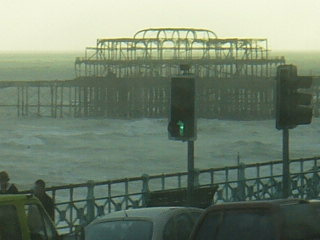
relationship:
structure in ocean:
[67, 32, 285, 94] [18, 112, 226, 173]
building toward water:
[79, 33, 283, 118] [11, 112, 132, 165]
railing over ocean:
[0, 153, 318, 239] [30, 133, 206, 173]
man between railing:
[25, 177, 55, 230] [72, 160, 310, 216]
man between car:
[25, 177, 55, 230] [2, 194, 52, 238]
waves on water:
[15, 125, 123, 146] [7, 116, 167, 160]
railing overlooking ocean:
[0, 153, 318, 239] [2, 49, 317, 235]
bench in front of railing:
[142, 182, 218, 205] [0, 153, 318, 239]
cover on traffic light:
[295, 74, 312, 88] [273, 61, 314, 129]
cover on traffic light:
[293, 91, 312, 107] [273, 61, 314, 129]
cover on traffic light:
[295, 106, 311, 129] [273, 61, 314, 129]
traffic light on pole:
[273, 61, 314, 129] [281, 127, 292, 199]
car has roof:
[66, 203, 209, 239] [86, 205, 205, 224]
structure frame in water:
[1, 26, 319, 124] [0, 50, 319, 236]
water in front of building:
[0, 50, 319, 236] [79, 33, 283, 118]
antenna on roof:
[121, 206, 129, 218] [84, 206, 208, 225]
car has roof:
[1, 187, 66, 238] [0, 191, 40, 206]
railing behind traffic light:
[0, 153, 318, 239] [273, 61, 314, 129]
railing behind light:
[0, 153, 318, 239] [167, 66, 197, 143]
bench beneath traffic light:
[142, 182, 218, 205] [167, 71, 199, 141]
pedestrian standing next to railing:
[28, 174, 60, 219] [0, 153, 318, 239]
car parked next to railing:
[66, 203, 209, 239] [0, 153, 318, 239]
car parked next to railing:
[1, 187, 66, 238] [0, 153, 318, 239]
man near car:
[25, 177, 55, 230] [0, 193, 63, 237]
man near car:
[25, 177, 55, 230] [66, 203, 209, 239]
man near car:
[0, 171, 17, 196] [0, 193, 63, 237]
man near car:
[0, 171, 17, 196] [66, 203, 209, 239]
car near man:
[186, 198, 319, 239] [28, 177, 57, 235]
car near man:
[186, 198, 319, 239] [0, 170, 17, 193]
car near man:
[70, 206, 208, 239] [28, 177, 57, 235]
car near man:
[70, 206, 208, 239] [0, 170, 17, 193]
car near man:
[1, 187, 66, 238] [28, 177, 57, 235]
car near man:
[1, 187, 66, 238] [0, 170, 17, 193]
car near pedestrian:
[1, 187, 66, 238] [28, 174, 60, 219]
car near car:
[66, 203, 209, 239] [1, 187, 66, 238]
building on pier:
[79, 33, 283, 118] [6, 72, 319, 119]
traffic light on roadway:
[164, 71, 203, 145] [70, 188, 317, 238]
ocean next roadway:
[11, 117, 152, 170] [70, 175, 319, 236]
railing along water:
[0, 153, 318, 239] [14, 114, 309, 168]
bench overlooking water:
[140, 181, 223, 205] [14, 114, 309, 168]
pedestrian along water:
[28, 174, 60, 219] [10, 116, 153, 170]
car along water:
[66, 203, 209, 239] [0, 115, 318, 180]